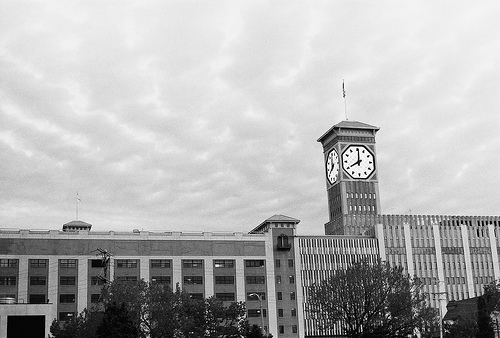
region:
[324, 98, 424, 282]
A clock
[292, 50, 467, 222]
A clock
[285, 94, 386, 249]
A clock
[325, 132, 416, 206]
A clock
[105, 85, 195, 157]
this is the sky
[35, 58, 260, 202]
the sky is big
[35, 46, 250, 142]
the sky is full of clouds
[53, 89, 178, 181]
the clouds are white in color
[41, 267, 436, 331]
these are some trees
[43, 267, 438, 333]
the trees are tall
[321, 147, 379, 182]
these are two clocks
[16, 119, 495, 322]
this is a building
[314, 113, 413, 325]
the building is tall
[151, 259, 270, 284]
there are several windows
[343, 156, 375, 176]
this is a clock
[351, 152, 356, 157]
the clock is white in color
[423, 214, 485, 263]
this is a building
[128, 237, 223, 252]
this is the wall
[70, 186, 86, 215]
this is a flag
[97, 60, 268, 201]
these are the clouds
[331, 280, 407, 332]
this is a tree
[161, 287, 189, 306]
the leaves are green in color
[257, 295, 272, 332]
this is a pole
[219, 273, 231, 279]
this is the window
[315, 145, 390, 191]
large clock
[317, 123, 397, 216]
large clock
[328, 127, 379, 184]
large clock